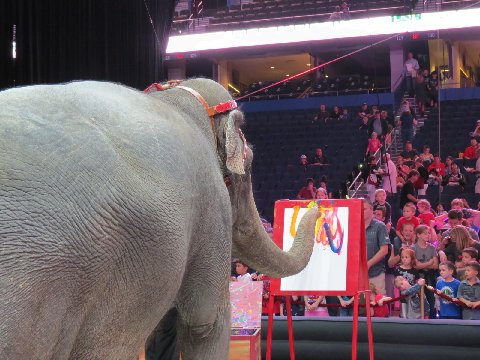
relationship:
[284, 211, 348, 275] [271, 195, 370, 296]
paper on easel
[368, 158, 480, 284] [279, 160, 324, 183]
spectators in seats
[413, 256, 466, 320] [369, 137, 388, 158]
boy wears shirt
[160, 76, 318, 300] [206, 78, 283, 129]
elephant wears harness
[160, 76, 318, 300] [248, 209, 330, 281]
elephant has trunks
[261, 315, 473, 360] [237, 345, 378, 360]
fence on stage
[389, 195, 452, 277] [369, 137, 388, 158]
kids wears shirt